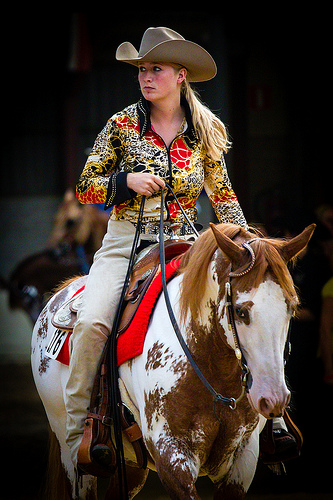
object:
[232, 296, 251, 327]
eye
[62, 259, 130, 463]
leg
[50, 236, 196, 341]
brown saddle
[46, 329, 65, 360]
176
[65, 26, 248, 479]
contestant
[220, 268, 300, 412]
face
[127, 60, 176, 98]
face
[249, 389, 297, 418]
nose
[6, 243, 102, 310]
horse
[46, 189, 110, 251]
horse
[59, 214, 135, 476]
pants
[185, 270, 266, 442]
skin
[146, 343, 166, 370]
brown marks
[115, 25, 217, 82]
hat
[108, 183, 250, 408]
thread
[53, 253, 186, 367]
blanket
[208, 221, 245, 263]
ears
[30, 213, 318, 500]
horse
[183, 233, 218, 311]
mane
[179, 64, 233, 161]
hair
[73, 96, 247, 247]
shirt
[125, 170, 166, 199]
hand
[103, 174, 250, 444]
reins